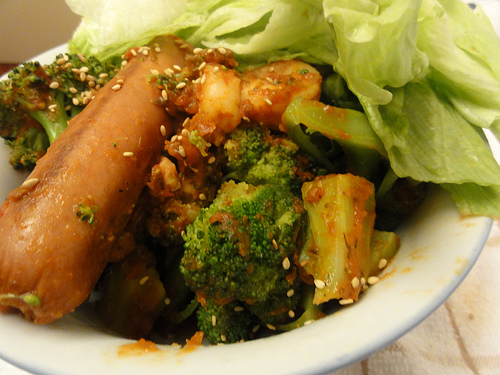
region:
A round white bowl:
[3, 23, 499, 373]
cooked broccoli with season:
[194, 183, 327, 333]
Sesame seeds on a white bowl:
[363, 264, 388, 296]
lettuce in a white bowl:
[54, 1, 485, 233]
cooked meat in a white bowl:
[30, 23, 199, 333]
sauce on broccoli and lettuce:
[323, 78, 377, 119]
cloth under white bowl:
[333, 229, 498, 370]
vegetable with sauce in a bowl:
[173, 33, 325, 163]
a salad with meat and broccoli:
[6, 14, 496, 374]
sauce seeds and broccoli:
[198, 158, 318, 325]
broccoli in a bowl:
[182, 147, 304, 345]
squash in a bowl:
[7, 32, 189, 314]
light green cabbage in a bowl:
[73, 0, 496, 222]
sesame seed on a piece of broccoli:
[350, 274, 360, 288]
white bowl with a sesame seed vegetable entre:
[1, 38, 497, 374]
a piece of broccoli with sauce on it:
[0, 58, 87, 143]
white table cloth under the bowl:
[326, 218, 499, 373]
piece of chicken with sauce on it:
[162, 63, 321, 156]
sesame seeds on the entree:
[50, 35, 390, 348]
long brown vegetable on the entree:
[2, 36, 202, 321]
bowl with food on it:
[1, 1, 499, 371]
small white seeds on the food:
[307, 256, 400, 311]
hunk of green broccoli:
[179, 182, 319, 339]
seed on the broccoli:
[273, 253, 294, 274]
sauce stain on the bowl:
[382, 255, 420, 280]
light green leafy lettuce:
[51, 1, 497, 202]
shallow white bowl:
[2, 28, 473, 374]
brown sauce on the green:
[307, 183, 372, 288]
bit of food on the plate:
[175, 329, 210, 359]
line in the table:
[448, 302, 475, 374]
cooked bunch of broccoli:
[180, 128, 397, 344]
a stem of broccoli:
[0, 51, 123, 159]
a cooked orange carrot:
[0, 33, 205, 323]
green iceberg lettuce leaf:
[61, 1, 498, 221]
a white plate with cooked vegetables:
[0, 38, 493, 373]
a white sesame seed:
[312, 277, 325, 289]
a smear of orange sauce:
[114, 335, 161, 355]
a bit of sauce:
[176, 329, 206, 356]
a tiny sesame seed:
[285, 286, 294, 296]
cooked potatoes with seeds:
[178, 57, 321, 153]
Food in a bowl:
[5, 8, 497, 325]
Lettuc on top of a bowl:
[60, 8, 498, 122]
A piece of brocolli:
[182, 186, 303, 297]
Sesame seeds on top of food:
[145, 66, 188, 99]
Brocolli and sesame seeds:
[3, 45, 105, 124]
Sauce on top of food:
[152, 41, 302, 183]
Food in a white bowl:
[2, 16, 499, 363]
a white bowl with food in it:
[10, 42, 395, 371]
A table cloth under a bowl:
[405, 264, 499, 374]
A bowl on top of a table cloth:
[238, 178, 499, 361]